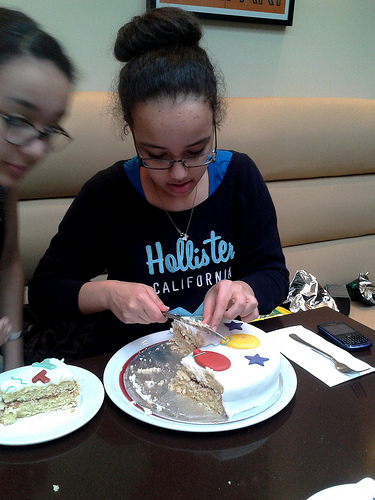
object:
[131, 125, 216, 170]
glasses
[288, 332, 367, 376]
fork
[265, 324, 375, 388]
napkin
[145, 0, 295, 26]
frame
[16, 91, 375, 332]
bench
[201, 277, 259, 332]
hand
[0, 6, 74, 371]
woman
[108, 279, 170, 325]
hand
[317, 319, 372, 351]
cell phone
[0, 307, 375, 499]
table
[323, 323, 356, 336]
screen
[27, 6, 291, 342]
girl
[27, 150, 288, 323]
black shirt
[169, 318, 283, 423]
cake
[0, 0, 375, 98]
wall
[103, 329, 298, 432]
plate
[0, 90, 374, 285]
back